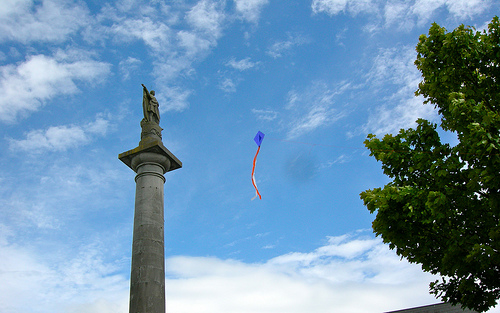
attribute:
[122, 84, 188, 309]
tower — gray, tall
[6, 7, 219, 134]
clouds — white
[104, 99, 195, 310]
pole — grey, concrete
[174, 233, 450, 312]
cloud — white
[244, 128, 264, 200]
kite — blue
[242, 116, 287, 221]
kite — blue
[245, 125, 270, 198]
kite — blue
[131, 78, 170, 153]
statue — grey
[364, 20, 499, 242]
tree — green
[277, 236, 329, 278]
clouds — white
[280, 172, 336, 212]
sky — blue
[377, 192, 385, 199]
leaf — green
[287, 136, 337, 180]
blue sky — distant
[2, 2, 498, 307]
clouds — white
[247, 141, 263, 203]
tail — long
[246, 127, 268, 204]
kite — blue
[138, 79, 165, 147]
statue — tall, stone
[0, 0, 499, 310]
sky — blue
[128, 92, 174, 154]
figure — stone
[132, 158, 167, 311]
pillar — tall, stone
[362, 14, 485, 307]
tree — tall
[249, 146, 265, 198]
tail — red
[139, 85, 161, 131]
figure — stone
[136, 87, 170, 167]
statue — large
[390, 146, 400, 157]
leaf — green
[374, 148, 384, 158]
leaf — green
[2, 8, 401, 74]
sky — blue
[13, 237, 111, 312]
clouds — white